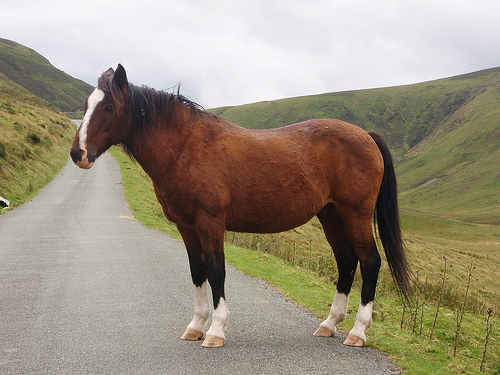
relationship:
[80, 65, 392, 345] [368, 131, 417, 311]
horse has tail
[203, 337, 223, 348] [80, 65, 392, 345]
hoof on horse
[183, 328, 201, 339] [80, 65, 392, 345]
hoof on horse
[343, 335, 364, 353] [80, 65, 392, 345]
hoof on horse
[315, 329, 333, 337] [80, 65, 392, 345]
hoof on horse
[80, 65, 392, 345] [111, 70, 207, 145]
horse has mane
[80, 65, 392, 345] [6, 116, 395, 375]
horse standing on concrete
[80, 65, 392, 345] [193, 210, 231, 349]
horse has leg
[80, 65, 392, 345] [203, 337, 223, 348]
horse has hoof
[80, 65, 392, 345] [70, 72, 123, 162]
horse has face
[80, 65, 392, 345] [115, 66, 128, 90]
horse has ear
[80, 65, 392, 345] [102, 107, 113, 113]
horse has eye